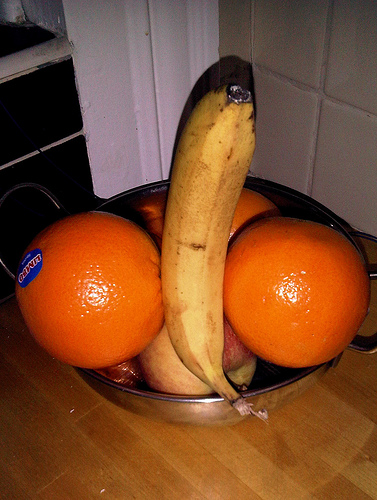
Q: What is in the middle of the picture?
A: Fruit.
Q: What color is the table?
A: Brown.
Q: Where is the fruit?
A: In a bowl.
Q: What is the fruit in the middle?
A: Banana.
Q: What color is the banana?
A: Yellow.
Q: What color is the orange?
A: Orange.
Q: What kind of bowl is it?
A: Metal.